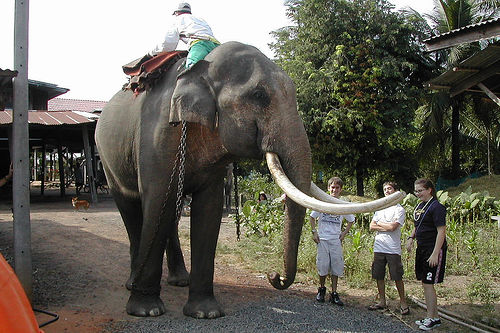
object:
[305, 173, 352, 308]
cow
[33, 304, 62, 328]
black cord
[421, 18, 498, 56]
roof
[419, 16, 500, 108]
building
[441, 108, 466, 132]
ground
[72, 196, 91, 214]
dog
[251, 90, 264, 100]
eye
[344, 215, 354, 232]
arm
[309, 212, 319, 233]
arm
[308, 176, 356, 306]
boy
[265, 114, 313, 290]
trunk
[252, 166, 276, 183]
floor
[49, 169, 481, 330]
field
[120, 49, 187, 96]
blanket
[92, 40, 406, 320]
elephant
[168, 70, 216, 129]
ear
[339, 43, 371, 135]
leaves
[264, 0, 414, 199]
tree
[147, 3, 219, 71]
man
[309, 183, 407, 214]
tusk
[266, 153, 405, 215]
tusk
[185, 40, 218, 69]
pants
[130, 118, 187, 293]
chain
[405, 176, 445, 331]
girl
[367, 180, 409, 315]
boy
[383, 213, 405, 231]
arms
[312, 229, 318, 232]
watch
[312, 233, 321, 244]
hand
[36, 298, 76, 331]
ground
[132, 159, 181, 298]
leg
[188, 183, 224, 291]
leg